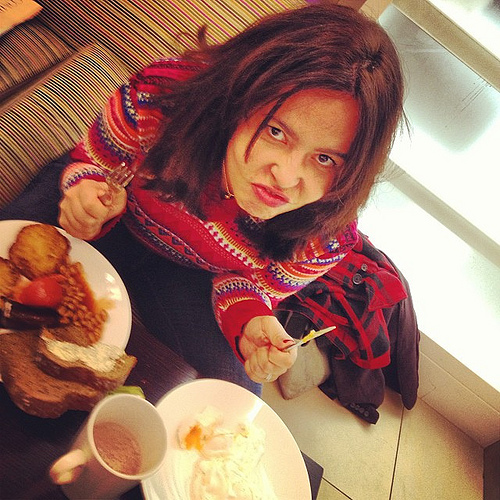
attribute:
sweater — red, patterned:
[59, 57, 358, 366]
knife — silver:
[278, 324, 336, 354]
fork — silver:
[101, 162, 136, 207]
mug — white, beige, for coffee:
[47, 394, 168, 500]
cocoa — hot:
[94, 421, 139, 475]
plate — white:
[140, 378, 313, 500]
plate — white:
[1, 220, 131, 352]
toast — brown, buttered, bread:
[3, 331, 138, 421]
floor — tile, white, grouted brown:
[255, 300, 483, 500]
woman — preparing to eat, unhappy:
[16, 9, 407, 403]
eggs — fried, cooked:
[162, 416, 276, 500]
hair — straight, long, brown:
[142, 6, 406, 269]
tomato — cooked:
[18, 278, 65, 307]